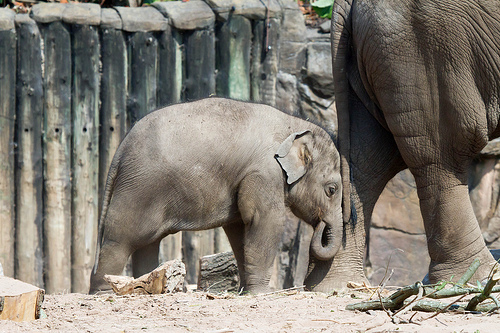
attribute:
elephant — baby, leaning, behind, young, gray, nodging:
[88, 96, 346, 294]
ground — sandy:
[7, 275, 495, 333]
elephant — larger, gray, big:
[332, 0, 500, 302]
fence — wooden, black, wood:
[2, 4, 262, 293]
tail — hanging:
[89, 128, 133, 274]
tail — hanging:
[329, 4, 356, 226]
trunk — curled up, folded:
[308, 215, 346, 262]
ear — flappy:
[274, 128, 319, 188]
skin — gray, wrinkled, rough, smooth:
[113, 107, 289, 226]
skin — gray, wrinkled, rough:
[343, 6, 499, 132]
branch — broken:
[422, 259, 500, 296]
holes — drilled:
[22, 126, 116, 136]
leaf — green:
[311, 2, 334, 19]